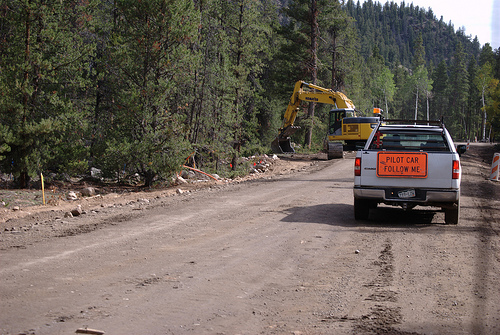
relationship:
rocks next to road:
[6, 149, 282, 220] [94, 159, 492, 334]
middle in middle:
[326, 141, 344, 160] [312, 135, 356, 165]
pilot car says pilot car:
[376, 150, 428, 178] [384, 154, 423, 166]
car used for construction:
[345, 111, 466, 229] [276, 72, 377, 158]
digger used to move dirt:
[276, 72, 377, 158] [233, 149, 330, 179]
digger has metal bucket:
[276, 72, 377, 158] [267, 131, 298, 157]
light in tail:
[351, 155, 363, 170] [350, 154, 364, 178]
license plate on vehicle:
[396, 188, 420, 201] [345, 111, 466, 229]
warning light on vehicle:
[372, 106, 382, 116] [276, 72, 377, 158]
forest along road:
[3, 2, 497, 80] [94, 159, 492, 334]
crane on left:
[276, 72, 377, 158] [92, 145, 325, 196]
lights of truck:
[353, 154, 466, 172] [345, 111, 466, 229]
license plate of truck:
[396, 188, 420, 201] [345, 111, 466, 229]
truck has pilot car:
[345, 111, 466, 229] [376, 150, 428, 178]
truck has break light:
[345, 111, 466, 229] [351, 155, 363, 170]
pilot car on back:
[376, 150, 428, 178] [352, 146, 463, 205]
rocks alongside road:
[6, 149, 282, 220] [94, 159, 492, 334]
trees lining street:
[3, 2, 497, 80] [94, 159, 492, 334]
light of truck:
[351, 155, 363, 170] [345, 111, 466, 229]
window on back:
[366, 127, 452, 151] [352, 146, 463, 205]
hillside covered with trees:
[3, 2, 497, 80] [10, 7, 477, 186]